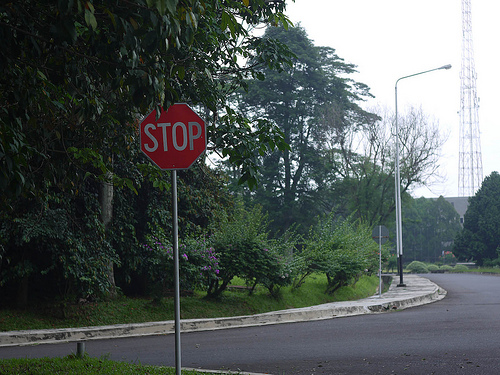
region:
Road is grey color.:
[395, 320, 458, 365]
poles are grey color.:
[390, 86, 408, 246]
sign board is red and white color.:
[137, 100, 213, 175]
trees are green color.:
[22, 192, 82, 277]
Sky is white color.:
[322, 7, 427, 39]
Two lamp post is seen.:
[386, 46, 448, 261]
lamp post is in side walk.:
[375, 235, 425, 305]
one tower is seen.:
[455, 8, 488, 199]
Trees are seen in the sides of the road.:
[46, 32, 307, 278]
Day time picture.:
[49, 34, 453, 345]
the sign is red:
[121, 86, 214, 194]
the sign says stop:
[135, 110, 214, 163]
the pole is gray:
[159, 164, 194, 357]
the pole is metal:
[161, 165, 199, 371]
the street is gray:
[37, 230, 486, 362]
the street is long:
[41, 230, 496, 374]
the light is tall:
[364, 40, 454, 287]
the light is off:
[422, 46, 457, 88]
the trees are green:
[58, 15, 138, 304]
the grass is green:
[211, 272, 287, 309]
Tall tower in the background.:
[453, 0, 482, 194]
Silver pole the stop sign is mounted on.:
[167, 171, 191, 373]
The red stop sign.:
[134, 103, 212, 170]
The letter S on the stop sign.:
[143, 121, 160, 152]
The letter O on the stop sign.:
[172, 123, 189, 153]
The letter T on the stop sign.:
[155, 118, 173, 152]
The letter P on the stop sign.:
[188, 92, 227, 115]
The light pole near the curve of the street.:
[388, 60, 458, 283]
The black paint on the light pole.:
[398, 248, 405, 288]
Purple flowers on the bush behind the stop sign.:
[146, 238, 223, 277]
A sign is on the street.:
[126, 97, 246, 372]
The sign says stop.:
[119, 92, 239, 179]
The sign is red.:
[132, 90, 221, 176]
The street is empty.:
[5, 265, 497, 372]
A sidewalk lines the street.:
[1, 265, 442, 351]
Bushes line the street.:
[63, 204, 372, 316]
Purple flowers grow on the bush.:
[133, 234, 228, 284]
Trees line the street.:
[0, 1, 338, 287]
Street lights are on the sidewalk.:
[366, 55, 459, 293]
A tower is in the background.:
[449, 2, 494, 212]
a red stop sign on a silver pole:
[129, 96, 215, 368]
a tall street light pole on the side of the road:
[380, 58, 454, 300]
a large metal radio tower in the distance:
[451, 5, 498, 258]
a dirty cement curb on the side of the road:
[199, 301, 341, 331]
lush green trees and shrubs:
[11, 28, 134, 298]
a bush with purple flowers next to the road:
[184, 239, 224, 290]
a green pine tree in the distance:
[455, 171, 498, 267]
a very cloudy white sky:
[328, 11, 438, 59]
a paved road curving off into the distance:
[313, 328, 485, 373]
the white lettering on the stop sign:
[141, 122, 202, 156]